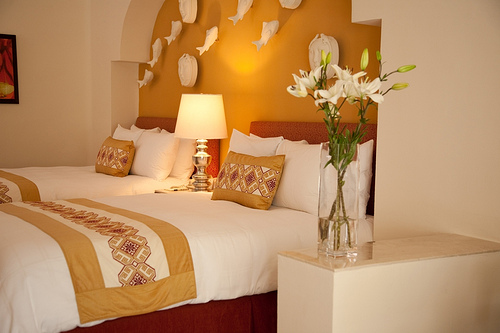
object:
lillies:
[337, 66, 386, 169]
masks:
[170, 52, 204, 90]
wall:
[130, 17, 497, 223]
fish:
[197, 25, 220, 52]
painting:
[1, 33, 22, 107]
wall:
[7, 10, 93, 174]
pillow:
[217, 155, 280, 206]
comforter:
[13, 192, 302, 255]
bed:
[10, 194, 318, 323]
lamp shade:
[169, 93, 236, 141]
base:
[185, 140, 217, 192]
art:
[143, 36, 169, 63]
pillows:
[127, 137, 174, 177]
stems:
[337, 188, 364, 247]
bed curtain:
[132, 297, 281, 333]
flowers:
[305, 55, 351, 177]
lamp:
[171, 91, 240, 194]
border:
[41, 199, 187, 314]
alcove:
[306, 37, 342, 76]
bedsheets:
[0, 193, 277, 309]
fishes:
[219, 0, 262, 27]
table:
[278, 245, 499, 325]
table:
[156, 180, 218, 200]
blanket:
[16, 193, 193, 306]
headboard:
[245, 116, 370, 153]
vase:
[319, 142, 363, 262]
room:
[6, 1, 496, 331]